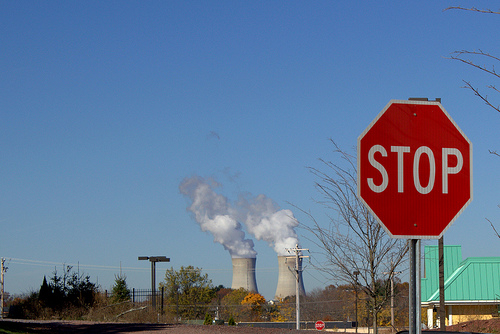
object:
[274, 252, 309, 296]
stacks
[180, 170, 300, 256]
pollution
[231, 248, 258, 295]
stacks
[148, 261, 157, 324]
poles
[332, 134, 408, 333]
branches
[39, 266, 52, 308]
trees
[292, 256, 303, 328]
poles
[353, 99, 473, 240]
sign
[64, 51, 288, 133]
sky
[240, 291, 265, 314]
trees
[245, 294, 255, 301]
leaves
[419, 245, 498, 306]
roof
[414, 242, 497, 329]
building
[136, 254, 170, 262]
light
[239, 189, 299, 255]
smoke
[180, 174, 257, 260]
smoke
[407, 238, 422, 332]
pole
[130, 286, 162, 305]
fence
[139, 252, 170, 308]
light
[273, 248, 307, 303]
building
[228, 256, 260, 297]
building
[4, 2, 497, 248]
sky